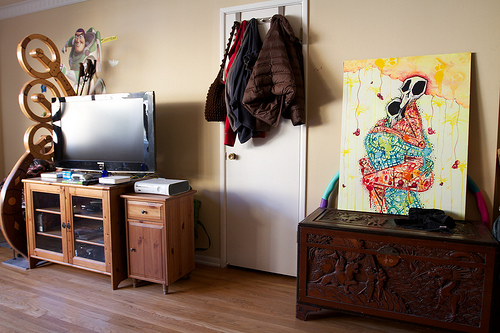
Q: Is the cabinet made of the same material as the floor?
A: Yes, both the cabinet and the floor are made of wood.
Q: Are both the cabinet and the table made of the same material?
A: Yes, both the cabinet and the table are made of wood.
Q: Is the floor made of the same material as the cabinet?
A: Yes, both the floor and the cabinet are made of wood.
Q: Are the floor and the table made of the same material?
A: Yes, both the floor and the table are made of wood.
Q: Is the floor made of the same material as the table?
A: Yes, both the floor and the table are made of wood.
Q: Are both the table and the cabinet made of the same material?
A: Yes, both the table and the cabinet are made of wood.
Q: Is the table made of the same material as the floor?
A: Yes, both the table and the floor are made of wood.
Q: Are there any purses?
A: Yes, there is a purse.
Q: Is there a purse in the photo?
A: Yes, there is a purse.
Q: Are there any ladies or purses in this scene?
A: Yes, there is a purse.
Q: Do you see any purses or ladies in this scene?
A: Yes, there is a purse.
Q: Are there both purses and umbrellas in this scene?
A: No, there is a purse but no umbrellas.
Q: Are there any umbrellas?
A: No, there are no umbrellas.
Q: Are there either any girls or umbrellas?
A: No, there are no umbrellas or girls.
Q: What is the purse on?
A: The purse is on the door.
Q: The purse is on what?
A: The purse is on the door.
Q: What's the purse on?
A: The purse is on the door.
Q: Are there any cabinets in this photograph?
A: Yes, there is a cabinet.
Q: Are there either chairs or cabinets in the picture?
A: Yes, there is a cabinet.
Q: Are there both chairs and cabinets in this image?
A: No, there is a cabinet but no chairs.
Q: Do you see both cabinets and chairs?
A: No, there is a cabinet but no chairs.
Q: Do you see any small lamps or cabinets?
A: Yes, there is a small cabinet.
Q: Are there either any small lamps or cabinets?
A: Yes, there is a small cabinet.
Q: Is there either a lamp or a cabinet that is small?
A: Yes, the cabinet is small.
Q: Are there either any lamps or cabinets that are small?
A: Yes, the cabinet is small.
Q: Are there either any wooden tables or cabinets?
A: Yes, there is a wood cabinet.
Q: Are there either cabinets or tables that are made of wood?
A: Yes, the cabinet is made of wood.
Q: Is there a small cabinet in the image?
A: Yes, there is a small cabinet.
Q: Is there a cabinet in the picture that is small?
A: Yes, there is a cabinet that is small.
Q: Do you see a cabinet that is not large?
A: Yes, there is a small cabinet.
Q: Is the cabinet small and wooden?
A: Yes, the cabinet is small and wooden.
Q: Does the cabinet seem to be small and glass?
A: No, the cabinet is small but wooden.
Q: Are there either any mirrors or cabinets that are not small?
A: No, there is a cabinet but it is small.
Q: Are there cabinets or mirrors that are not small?
A: No, there is a cabinet but it is small.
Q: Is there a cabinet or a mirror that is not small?
A: No, there is a cabinet but it is small.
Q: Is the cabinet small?
A: Yes, the cabinet is small.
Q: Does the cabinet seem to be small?
A: Yes, the cabinet is small.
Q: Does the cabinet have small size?
A: Yes, the cabinet is small.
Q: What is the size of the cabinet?
A: The cabinet is small.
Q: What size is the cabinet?
A: The cabinet is small.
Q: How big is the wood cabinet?
A: The cabinet is small.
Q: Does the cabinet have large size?
A: No, the cabinet is small.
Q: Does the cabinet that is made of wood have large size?
A: No, the cabinet is small.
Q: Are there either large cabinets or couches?
A: No, there is a cabinet but it is small.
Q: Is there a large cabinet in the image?
A: No, there is a cabinet but it is small.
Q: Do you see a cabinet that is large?
A: No, there is a cabinet but it is small.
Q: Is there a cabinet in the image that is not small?
A: No, there is a cabinet but it is small.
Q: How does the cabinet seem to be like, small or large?
A: The cabinet is small.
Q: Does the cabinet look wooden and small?
A: Yes, the cabinet is wooden and small.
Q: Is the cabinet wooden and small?
A: Yes, the cabinet is wooden and small.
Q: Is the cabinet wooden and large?
A: No, the cabinet is wooden but small.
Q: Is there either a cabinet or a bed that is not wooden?
A: No, there is a cabinet but it is wooden.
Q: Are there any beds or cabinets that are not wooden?
A: No, there is a cabinet but it is wooden.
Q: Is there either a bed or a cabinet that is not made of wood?
A: No, there is a cabinet but it is made of wood.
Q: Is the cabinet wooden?
A: Yes, the cabinet is wooden.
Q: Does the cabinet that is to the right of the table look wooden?
A: Yes, the cabinet is wooden.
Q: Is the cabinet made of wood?
A: Yes, the cabinet is made of wood.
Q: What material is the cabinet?
A: The cabinet is made of wood.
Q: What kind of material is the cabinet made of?
A: The cabinet is made of wood.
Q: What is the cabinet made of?
A: The cabinet is made of wood.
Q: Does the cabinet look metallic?
A: No, the cabinet is wooden.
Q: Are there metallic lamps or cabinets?
A: No, there is a cabinet but it is wooden.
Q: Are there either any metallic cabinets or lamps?
A: No, there is a cabinet but it is wooden.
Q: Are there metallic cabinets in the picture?
A: No, there is a cabinet but it is wooden.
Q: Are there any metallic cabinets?
A: No, there is a cabinet but it is wooden.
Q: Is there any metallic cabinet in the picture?
A: No, there is a cabinet but it is wooden.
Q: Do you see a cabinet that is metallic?
A: No, there is a cabinet but it is wooden.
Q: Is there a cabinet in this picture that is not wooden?
A: No, there is a cabinet but it is wooden.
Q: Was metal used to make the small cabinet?
A: No, the cabinet is made of wood.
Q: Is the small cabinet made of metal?
A: No, the cabinet is made of wood.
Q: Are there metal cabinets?
A: No, there is a cabinet but it is made of wood.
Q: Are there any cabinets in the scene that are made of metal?
A: No, there is a cabinet but it is made of wood.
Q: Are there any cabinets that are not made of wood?
A: No, there is a cabinet but it is made of wood.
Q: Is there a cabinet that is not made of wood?
A: No, there is a cabinet but it is made of wood.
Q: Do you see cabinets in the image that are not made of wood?
A: No, there is a cabinet but it is made of wood.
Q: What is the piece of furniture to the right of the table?
A: The piece of furniture is a cabinet.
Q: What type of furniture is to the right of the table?
A: The piece of furniture is a cabinet.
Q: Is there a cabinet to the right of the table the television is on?
A: Yes, there is a cabinet to the right of the table.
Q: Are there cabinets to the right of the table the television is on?
A: Yes, there is a cabinet to the right of the table.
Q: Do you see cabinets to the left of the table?
A: No, the cabinet is to the right of the table.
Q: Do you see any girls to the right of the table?
A: No, there is a cabinet to the right of the table.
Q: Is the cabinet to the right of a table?
A: Yes, the cabinet is to the right of a table.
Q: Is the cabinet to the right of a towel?
A: No, the cabinet is to the right of a table.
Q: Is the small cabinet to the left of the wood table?
A: No, the cabinet is to the right of the table.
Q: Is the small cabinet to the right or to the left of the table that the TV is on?
A: The cabinet is to the right of the table.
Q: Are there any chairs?
A: No, there are no chairs.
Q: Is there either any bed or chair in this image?
A: No, there are no chairs or beds.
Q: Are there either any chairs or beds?
A: No, there are no chairs or beds.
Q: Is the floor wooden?
A: Yes, the floor is wooden.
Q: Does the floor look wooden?
A: Yes, the floor is wooden.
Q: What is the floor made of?
A: The floor is made of wood.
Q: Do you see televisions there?
A: Yes, there is a television.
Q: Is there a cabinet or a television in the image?
A: Yes, there is a television.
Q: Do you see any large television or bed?
A: Yes, there is a large television.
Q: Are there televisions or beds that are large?
A: Yes, the television is large.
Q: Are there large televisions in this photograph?
A: Yes, there is a large television.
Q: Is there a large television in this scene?
A: Yes, there is a large television.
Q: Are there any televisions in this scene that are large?
A: Yes, there is a television that is large.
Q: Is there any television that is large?
A: Yes, there is a television that is large.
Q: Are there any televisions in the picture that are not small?
A: Yes, there is a large television.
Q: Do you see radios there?
A: No, there are no radios.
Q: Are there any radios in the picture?
A: No, there are no radios.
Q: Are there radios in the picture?
A: No, there are no radios.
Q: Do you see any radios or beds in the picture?
A: No, there are no radios or beds.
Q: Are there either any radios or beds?
A: No, there are no radios or beds.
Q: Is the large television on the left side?
A: Yes, the television is on the left of the image.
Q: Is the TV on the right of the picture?
A: No, the TV is on the left of the image.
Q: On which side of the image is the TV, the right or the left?
A: The TV is on the left of the image.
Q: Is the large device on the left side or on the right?
A: The TV is on the left of the image.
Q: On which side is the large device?
A: The television is on the left of the image.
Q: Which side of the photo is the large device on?
A: The television is on the left of the image.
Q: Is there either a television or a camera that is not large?
A: No, there is a television but it is large.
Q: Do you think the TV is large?
A: Yes, the TV is large.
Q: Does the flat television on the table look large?
A: Yes, the TV is large.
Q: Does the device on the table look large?
A: Yes, the TV is large.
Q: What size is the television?
A: The television is large.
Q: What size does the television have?
A: The television has large size.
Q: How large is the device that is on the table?
A: The television is large.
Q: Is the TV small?
A: No, the TV is large.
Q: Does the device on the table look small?
A: No, the television is large.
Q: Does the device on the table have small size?
A: No, the television is large.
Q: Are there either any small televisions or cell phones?
A: No, there is a television but it is large.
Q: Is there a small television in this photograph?
A: No, there is a television but it is large.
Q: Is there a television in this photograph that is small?
A: No, there is a television but it is large.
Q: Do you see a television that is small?
A: No, there is a television but it is large.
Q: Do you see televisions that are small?
A: No, there is a television but it is large.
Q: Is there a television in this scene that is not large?
A: No, there is a television but it is large.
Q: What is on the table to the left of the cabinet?
A: The television is on the table.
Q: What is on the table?
A: The television is on the table.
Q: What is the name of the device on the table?
A: The device is a television.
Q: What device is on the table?
A: The device is a television.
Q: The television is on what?
A: The television is on the table.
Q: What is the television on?
A: The television is on the table.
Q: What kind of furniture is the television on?
A: The television is on the table.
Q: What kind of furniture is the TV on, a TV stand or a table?
A: The TV is on a table.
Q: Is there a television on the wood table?
A: Yes, there is a television on the table.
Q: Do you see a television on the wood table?
A: Yes, there is a television on the table.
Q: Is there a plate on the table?
A: No, there is a television on the table.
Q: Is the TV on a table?
A: Yes, the TV is on a table.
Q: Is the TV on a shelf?
A: No, the TV is on a table.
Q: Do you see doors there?
A: Yes, there are doors.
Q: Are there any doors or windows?
A: Yes, there are doors.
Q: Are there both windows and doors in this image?
A: No, there are doors but no windows.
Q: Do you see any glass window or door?
A: Yes, there are glass doors.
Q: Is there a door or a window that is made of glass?
A: Yes, the doors are made of glass.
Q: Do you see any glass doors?
A: Yes, there are doors that are made of glass.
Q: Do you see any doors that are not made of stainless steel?
A: Yes, there are doors that are made of glass.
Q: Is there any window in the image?
A: No, there are no windows.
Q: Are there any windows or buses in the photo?
A: No, there are no windows or buses.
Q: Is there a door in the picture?
A: Yes, there is a door.